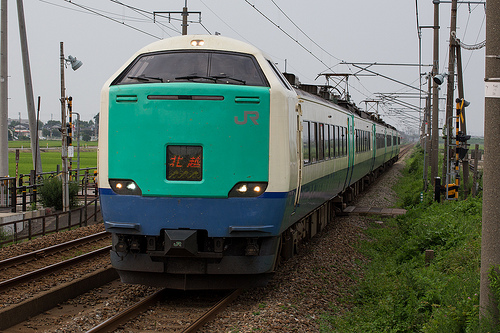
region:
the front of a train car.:
[84, 19, 292, 288]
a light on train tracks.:
[50, 39, 95, 218]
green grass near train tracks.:
[346, 144, 497, 330]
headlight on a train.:
[96, 174, 143, 202]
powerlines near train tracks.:
[226, 0, 426, 137]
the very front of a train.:
[149, 131, 216, 191]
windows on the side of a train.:
[284, 111, 366, 176]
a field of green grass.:
[0, 130, 95, 185]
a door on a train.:
[341, 111, 358, 193]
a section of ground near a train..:
[326, 251, 343, 283]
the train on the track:
[98, 22, 405, 286]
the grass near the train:
[382, 151, 443, 329]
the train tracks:
[42, 293, 225, 331]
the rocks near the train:
[263, 250, 331, 331]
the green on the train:
[112, 105, 163, 186]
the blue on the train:
[110, 200, 187, 223]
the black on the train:
[111, 248, 166, 269]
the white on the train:
[275, 105, 293, 175]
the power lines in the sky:
[246, 1, 375, 91]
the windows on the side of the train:
[297, 94, 399, 183]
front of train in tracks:
[80, 23, 308, 263]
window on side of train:
[290, 117, 305, 162]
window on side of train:
[308, 122, 318, 159]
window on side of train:
[321, 125, 331, 157]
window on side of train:
[325, 125, 335, 160]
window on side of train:
[335, 127, 345, 154]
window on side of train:
[351, 131, 361, 150]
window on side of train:
[359, 130, 370, 148]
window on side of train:
[374, 132, 379, 144]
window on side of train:
[386, 132, 389, 144]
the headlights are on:
[62, 155, 291, 211]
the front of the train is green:
[87, 40, 280, 194]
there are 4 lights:
[65, 167, 267, 195]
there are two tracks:
[3, 237, 221, 329]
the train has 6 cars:
[113, 63, 431, 221]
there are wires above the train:
[183, 8, 385, 115]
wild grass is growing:
[366, 139, 490, 323]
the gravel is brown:
[222, 205, 363, 326]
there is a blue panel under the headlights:
[75, 183, 290, 243]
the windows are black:
[109, 49, 259, 91]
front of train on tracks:
[99, 52, 269, 302]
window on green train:
[128, 50, 259, 87]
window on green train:
[296, 117, 310, 162]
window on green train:
[309, 126, 318, 166]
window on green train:
[321, 125, 328, 158]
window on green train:
[333, 125, 338, 155]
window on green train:
[338, 128, 349, 153]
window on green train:
[350, 127, 361, 152]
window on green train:
[372, 135, 380, 147]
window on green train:
[380, 135, 385, 147]